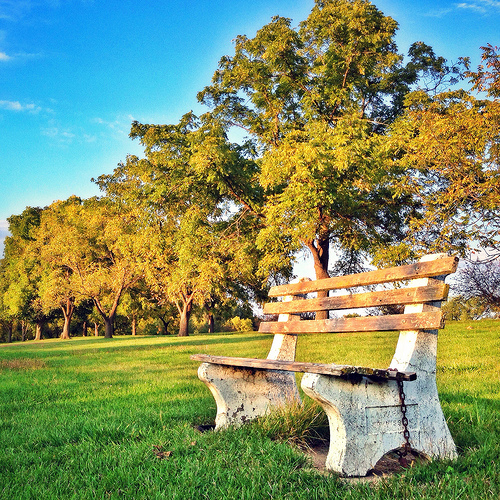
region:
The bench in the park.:
[220, 248, 433, 471]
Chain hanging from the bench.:
[390, 375, 411, 460]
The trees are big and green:
[46, 212, 243, 298]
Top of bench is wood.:
[272, 280, 442, 328]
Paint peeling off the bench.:
[230, 375, 305, 405]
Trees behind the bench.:
[35, 212, 447, 317]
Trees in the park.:
[55, 211, 405, 292]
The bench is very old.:
[218, 271, 436, 438]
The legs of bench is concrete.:
[287, 375, 492, 460]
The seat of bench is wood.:
[217, 353, 412, 390]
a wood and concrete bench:
[192, 254, 459, 473]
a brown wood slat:
[259, 312, 444, 331]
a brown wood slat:
[263, 283, 448, 315]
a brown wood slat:
[265, 253, 457, 296]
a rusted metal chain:
[397, 370, 414, 467]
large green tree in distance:
[184, 1, 444, 323]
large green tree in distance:
[105, 118, 263, 333]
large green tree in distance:
[57, 195, 144, 340]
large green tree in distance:
[25, 198, 93, 334]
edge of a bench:
[338, 417, 347, 438]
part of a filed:
[124, 350, 165, 412]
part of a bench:
[405, 382, 432, 429]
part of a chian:
[395, 406, 425, 456]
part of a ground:
[160, 442, 207, 498]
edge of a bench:
[331, 427, 351, 483]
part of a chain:
[397, 391, 432, 436]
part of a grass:
[310, 418, 326, 445]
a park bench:
[152, 242, 468, 478]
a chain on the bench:
[382, 364, 428, 456]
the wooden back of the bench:
[246, 250, 462, 335]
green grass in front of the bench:
[25, 397, 170, 474]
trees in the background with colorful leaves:
[30, 195, 245, 335]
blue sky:
[70, 17, 173, 99]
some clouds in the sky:
[11, 91, 127, 151]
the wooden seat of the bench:
[171, 336, 426, 411]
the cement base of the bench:
[291, 365, 467, 475]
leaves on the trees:
[265, 44, 363, 101]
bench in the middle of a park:
[180, 248, 468, 473]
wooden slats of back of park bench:
[252, 268, 459, 335]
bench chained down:
[377, 363, 429, 473]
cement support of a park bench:
[205, 370, 292, 425]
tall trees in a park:
[11, 212, 216, 342]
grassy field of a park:
[34, 345, 131, 455]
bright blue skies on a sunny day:
[39, 16, 175, 89]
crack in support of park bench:
[394, 350, 436, 375]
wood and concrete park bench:
[188, 250, 467, 475]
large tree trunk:
[305, 240, 335, 326]